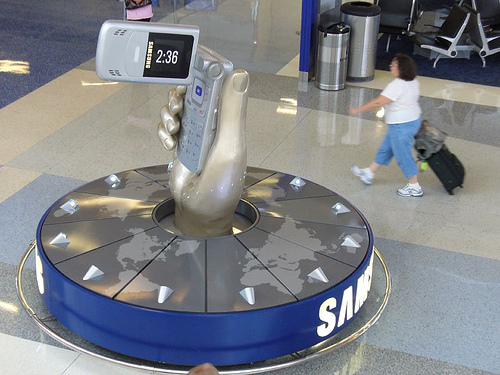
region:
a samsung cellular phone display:
[15, 18, 391, 373]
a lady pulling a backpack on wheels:
[348, 52, 465, 197]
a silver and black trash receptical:
[340, 0, 380, 80]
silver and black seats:
[413, 4, 470, 67]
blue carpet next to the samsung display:
[0, 0, 192, 109]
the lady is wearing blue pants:
[375, 115, 421, 177]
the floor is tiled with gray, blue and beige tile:
[0, 0, 498, 373]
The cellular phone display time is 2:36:
[93, 18, 232, 174]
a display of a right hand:
[158, 69, 250, 233]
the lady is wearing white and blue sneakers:
[395, 183, 422, 195]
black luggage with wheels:
[425, 145, 482, 197]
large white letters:
[145, 43, 188, 70]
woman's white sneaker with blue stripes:
[348, 161, 385, 190]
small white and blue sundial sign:
[233, 275, 271, 321]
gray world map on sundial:
[107, 225, 202, 278]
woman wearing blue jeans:
[372, 113, 450, 185]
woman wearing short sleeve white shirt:
[366, 79, 433, 128]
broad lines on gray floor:
[5, 51, 65, 96]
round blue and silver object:
[22, 126, 400, 374]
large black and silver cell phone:
[81, 3, 246, 188]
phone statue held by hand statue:
[91, 19, 237, 169]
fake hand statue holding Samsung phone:
[97, 16, 256, 235]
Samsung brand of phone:
[145, 39, 152, 71]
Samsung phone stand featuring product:
[26, 17, 374, 373]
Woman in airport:
[347, 50, 427, 198]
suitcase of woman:
[406, 120, 471, 195]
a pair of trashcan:
[315, 0, 375, 85]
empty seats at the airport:
[415, 0, 495, 62]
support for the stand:
[17, 235, 397, 372]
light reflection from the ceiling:
[273, 93, 305, 118]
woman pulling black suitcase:
[346, 39, 468, 216]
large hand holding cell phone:
[83, 5, 301, 254]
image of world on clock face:
[51, 153, 339, 333]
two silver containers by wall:
[306, 0, 386, 95]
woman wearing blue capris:
[363, 114, 444, 219]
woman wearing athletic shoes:
[344, 158, 430, 213]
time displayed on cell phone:
[133, 30, 198, 89]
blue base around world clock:
[23, 223, 393, 365]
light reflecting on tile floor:
[267, 93, 319, 128]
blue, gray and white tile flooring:
[131, 36, 458, 360]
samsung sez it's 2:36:
[154, 48, 178, 65]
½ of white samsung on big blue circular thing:
[313, 242, 377, 344]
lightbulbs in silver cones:
[44, 161, 362, 310]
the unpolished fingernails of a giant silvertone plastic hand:
[151, 63, 262, 155]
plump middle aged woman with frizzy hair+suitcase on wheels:
[340, 48, 471, 203]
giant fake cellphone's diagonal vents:
[100, 24, 134, 78]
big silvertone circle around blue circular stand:
[12, 181, 398, 372]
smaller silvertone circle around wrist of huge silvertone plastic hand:
[145, 190, 262, 240]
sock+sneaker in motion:
[347, 161, 378, 187]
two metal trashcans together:
[308, 0, 385, 105]